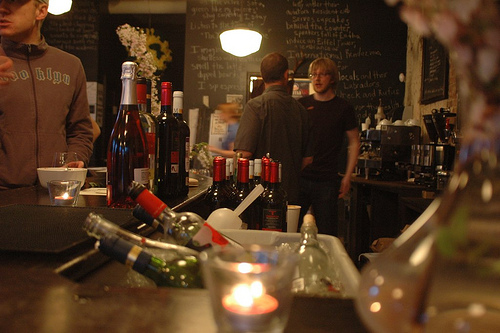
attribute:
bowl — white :
[34, 163, 93, 193]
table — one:
[5, 159, 215, 263]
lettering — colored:
[2, 62, 73, 87]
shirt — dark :
[283, 88, 354, 198]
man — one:
[270, 50, 355, 222]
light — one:
[210, 14, 264, 72]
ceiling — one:
[140, 1, 388, 16]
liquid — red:
[100, 64, 150, 207]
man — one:
[287, 47, 362, 221]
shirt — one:
[286, 83, 349, 177]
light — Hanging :
[217, 28, 260, 59]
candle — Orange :
[226, 277, 278, 331]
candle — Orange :
[46, 183, 83, 210]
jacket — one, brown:
[2, 40, 99, 194]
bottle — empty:
[89, 217, 208, 298]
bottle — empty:
[132, 182, 239, 260]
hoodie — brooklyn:
[0, 35, 97, 193]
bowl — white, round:
[34, 162, 88, 191]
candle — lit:
[198, 238, 298, 328]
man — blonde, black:
[287, 53, 366, 235]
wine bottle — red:
[107, 51, 151, 223]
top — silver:
[114, 55, 144, 103]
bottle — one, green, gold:
[94, 228, 208, 284]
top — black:
[80, 236, 150, 266]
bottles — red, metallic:
[206, 152, 283, 223]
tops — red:
[213, 158, 284, 186]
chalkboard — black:
[185, 35, 247, 115]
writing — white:
[195, 45, 237, 85]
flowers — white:
[114, 22, 155, 78]